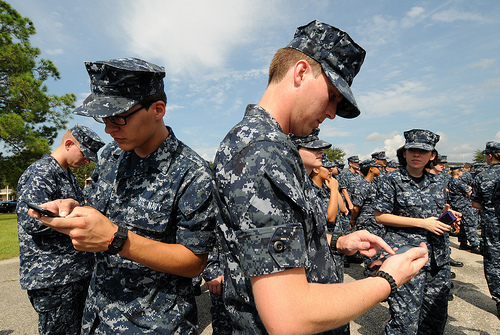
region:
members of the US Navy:
[17, 20, 497, 330]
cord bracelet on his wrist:
[370, 270, 400, 297]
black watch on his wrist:
[101, 225, 128, 256]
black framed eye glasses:
[88, 107, 142, 124]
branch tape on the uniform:
[134, 200, 163, 212]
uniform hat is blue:
[76, 58, 166, 117]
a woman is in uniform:
[381, 128, 456, 331]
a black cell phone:
[367, 236, 425, 278]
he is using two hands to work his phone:
[28, 196, 118, 253]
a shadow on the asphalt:
[449, 273, 498, 315]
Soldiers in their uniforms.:
[11, 17, 496, 332]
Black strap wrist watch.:
[103, 224, 130, 252]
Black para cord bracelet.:
[371, 270, 398, 295]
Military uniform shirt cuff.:
[233, 223, 307, 274]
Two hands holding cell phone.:
[28, 199, 106, 250]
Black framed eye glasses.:
[93, 101, 146, 126]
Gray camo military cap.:
[75, 59, 166, 116]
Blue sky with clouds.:
[7, 1, 499, 158]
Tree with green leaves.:
[1, 2, 78, 164]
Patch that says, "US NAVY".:
[133, 198, 164, 212]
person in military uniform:
[371, 121, 464, 332]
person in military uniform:
[214, 19, 364, 332]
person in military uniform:
[75, 60, 204, 332]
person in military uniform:
[12, 125, 87, 333]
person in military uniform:
[471, 143, 498, 311]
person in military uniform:
[357, 158, 377, 233]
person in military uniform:
[338, 147, 358, 199]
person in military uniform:
[317, 153, 332, 203]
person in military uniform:
[442, 161, 470, 241]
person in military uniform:
[434, 158, 451, 195]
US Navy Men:
[26, 16, 458, 333]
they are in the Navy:
[23, 2, 494, 332]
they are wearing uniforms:
[1, 9, 496, 334]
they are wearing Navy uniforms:
[4, 17, 496, 334]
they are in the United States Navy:
[28, 14, 498, 331]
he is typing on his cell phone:
[21, 36, 235, 325]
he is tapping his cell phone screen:
[201, 4, 496, 334]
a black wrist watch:
[102, 209, 149, 290]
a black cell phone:
[16, 184, 96, 236]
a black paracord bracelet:
[358, 259, 420, 318]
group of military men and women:
[16, 20, 497, 331]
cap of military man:
[290, 18, 365, 118]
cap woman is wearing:
[400, 130, 440, 151]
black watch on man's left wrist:
[105, 220, 126, 253]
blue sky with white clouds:
[0, 0, 497, 161]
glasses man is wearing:
[91, 106, 147, 124]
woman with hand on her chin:
[310, 157, 336, 218]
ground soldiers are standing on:
[0, 215, 498, 332]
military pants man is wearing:
[25, 287, 81, 334]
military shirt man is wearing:
[214, 106, 351, 333]